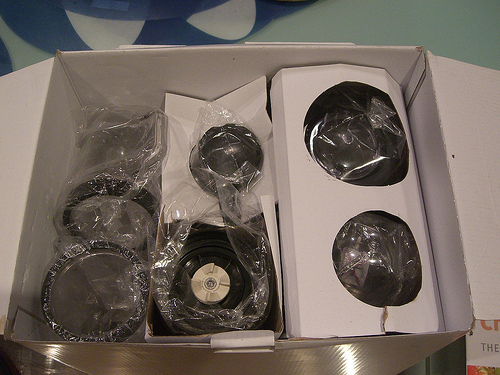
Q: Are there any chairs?
A: No, there are no chairs.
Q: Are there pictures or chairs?
A: No, there are no chairs or pictures.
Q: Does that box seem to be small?
A: Yes, the box is small.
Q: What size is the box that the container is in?
A: The box is small.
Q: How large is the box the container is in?
A: The box is small.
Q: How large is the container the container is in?
A: The box is small.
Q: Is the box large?
A: No, the box is small.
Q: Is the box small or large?
A: The box is small.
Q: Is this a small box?
A: Yes, this is a small box.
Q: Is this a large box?
A: No, this is a small box.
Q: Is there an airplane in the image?
A: No, there are no airplanes.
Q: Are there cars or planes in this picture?
A: No, there are no planes or cars.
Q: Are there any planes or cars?
A: No, there are no planes or cars.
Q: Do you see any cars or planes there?
A: No, there are no planes or cars.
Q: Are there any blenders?
A: Yes, there is a blender.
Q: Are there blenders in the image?
A: Yes, there is a blender.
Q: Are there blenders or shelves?
A: Yes, there is a blender.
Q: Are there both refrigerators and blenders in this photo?
A: No, there is a blender but no refrigerators.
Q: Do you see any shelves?
A: No, there are no shelves.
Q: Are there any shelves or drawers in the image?
A: No, there are no shelves or drawers.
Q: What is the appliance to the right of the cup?
A: The appliance is a blender.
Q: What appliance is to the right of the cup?
A: The appliance is a blender.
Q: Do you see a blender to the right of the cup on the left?
A: Yes, there is a blender to the right of the cup.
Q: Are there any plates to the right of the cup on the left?
A: No, there is a blender to the right of the cup.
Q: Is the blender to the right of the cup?
A: Yes, the blender is to the right of the cup.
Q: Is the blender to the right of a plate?
A: No, the blender is to the right of the cup.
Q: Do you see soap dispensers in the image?
A: No, there are no soap dispensers.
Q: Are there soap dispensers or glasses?
A: No, there are no soap dispensers or glasses.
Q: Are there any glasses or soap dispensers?
A: No, there are no soap dispensers or glasses.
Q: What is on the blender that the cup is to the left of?
A: The ring is on the blender.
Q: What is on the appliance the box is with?
A: The ring is on the blender.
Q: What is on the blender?
A: The ring is on the blender.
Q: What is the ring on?
A: The ring is on the blender.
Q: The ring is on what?
A: The ring is on the blender.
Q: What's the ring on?
A: The ring is on the blender.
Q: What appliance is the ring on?
A: The ring is on the blender.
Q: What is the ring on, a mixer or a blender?
A: The ring is on a blender.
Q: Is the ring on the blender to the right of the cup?
A: Yes, the ring is on the blender.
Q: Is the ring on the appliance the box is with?
A: Yes, the ring is on the blender.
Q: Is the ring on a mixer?
A: No, the ring is on the blender.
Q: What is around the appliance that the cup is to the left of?
A: The ring is around the blender.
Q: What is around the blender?
A: The ring is around the blender.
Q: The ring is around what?
A: The ring is around the blender.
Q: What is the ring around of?
A: The ring is around the blender.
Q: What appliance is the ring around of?
A: The ring is around the blender.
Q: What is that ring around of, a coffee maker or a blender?
A: The ring is around a blender.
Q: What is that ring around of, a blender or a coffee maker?
A: The ring is around a blender.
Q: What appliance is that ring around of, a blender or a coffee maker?
A: The ring is around a blender.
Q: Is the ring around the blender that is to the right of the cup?
A: Yes, the ring is around the blender.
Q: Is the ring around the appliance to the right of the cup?
A: Yes, the ring is around the blender.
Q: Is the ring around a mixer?
A: No, the ring is around the blender.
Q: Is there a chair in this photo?
A: No, there are no chairs.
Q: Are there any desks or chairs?
A: No, there are no chairs or desks.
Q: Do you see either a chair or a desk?
A: No, there are no chairs or desks.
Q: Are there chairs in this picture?
A: No, there are no chairs.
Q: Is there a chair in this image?
A: No, there are no chairs.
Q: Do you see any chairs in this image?
A: No, there are no chairs.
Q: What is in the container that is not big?
A: The container is in the box.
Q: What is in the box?
A: The container is in the box.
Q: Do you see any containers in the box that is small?
A: Yes, there is a container in the box.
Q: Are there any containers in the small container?
A: Yes, there is a container in the box.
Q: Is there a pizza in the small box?
A: No, there is a container in the box.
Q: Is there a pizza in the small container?
A: No, there is a container in the box.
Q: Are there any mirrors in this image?
A: No, there are no mirrors.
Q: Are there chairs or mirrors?
A: No, there are no mirrors or chairs.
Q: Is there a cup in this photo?
A: Yes, there is a cup.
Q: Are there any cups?
A: Yes, there is a cup.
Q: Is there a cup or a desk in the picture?
A: Yes, there is a cup.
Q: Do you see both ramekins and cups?
A: No, there is a cup but no ramekins.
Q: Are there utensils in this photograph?
A: No, there are no utensils.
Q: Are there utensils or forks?
A: No, there are no utensils or forks.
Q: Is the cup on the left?
A: Yes, the cup is on the left of the image.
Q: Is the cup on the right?
A: No, the cup is on the left of the image.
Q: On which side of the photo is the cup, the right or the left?
A: The cup is on the left of the image.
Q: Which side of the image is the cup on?
A: The cup is on the left of the image.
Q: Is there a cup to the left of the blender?
A: Yes, there is a cup to the left of the blender.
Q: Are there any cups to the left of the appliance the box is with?
A: Yes, there is a cup to the left of the blender.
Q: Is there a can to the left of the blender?
A: No, there is a cup to the left of the blender.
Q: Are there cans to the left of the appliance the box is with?
A: No, there is a cup to the left of the blender.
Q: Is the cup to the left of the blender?
A: Yes, the cup is to the left of the blender.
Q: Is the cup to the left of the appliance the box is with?
A: Yes, the cup is to the left of the blender.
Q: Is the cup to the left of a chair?
A: No, the cup is to the left of the blender.